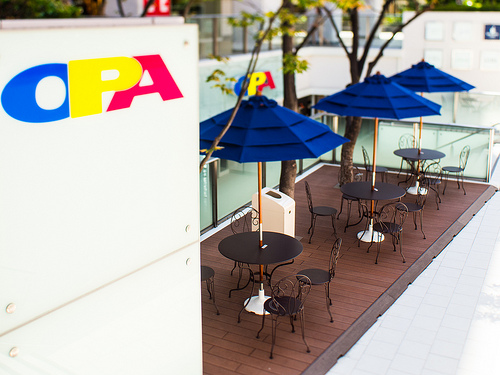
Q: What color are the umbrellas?
A: Blue.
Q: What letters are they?
A: Opa.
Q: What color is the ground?
A: Brown.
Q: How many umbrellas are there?
A: Three.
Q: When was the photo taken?
A: Daytime.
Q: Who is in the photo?
A: No one.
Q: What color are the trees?
A: Green.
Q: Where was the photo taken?
A: In a restaurant.